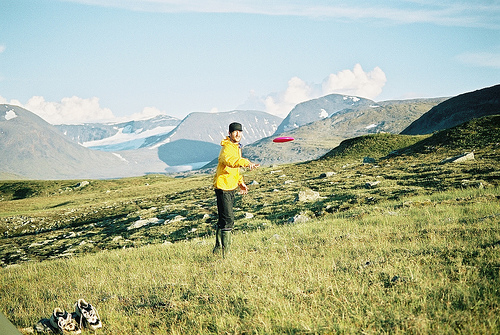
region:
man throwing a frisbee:
[196, 102, 336, 261]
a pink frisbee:
[256, 117, 305, 157]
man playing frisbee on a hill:
[191, 87, 343, 262]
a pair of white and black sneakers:
[34, 290, 116, 334]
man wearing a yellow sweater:
[208, 138, 254, 190]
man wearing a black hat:
[225, 122, 250, 134]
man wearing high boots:
[206, 225, 247, 261]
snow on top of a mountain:
[2, 96, 37, 136]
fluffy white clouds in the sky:
[280, 62, 398, 97]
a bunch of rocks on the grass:
[270, 163, 350, 225]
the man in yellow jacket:
[131, 89, 302, 323]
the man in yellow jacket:
[195, 112, 331, 326]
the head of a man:
[226, 119, 249, 144]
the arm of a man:
[219, 146, 244, 170]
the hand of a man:
[242, 158, 262, 175]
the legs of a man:
[208, 182, 243, 254]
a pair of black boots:
[207, 227, 232, 259]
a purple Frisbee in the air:
[271, 130, 296, 147]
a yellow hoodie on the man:
[209, 136, 251, 191]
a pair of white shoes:
[51, 290, 110, 333]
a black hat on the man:
[226, 116, 246, 132]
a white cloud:
[238, 55, 395, 118]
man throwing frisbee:
[210, 120, 296, 267]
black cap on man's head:
[226, 119, 244, 131]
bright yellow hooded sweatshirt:
[212, 133, 244, 190]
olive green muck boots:
[212, 225, 239, 259]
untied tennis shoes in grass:
[42, 297, 103, 333]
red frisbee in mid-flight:
[270, 133, 291, 141]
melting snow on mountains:
[46, 115, 194, 152]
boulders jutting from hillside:
[293, 181, 321, 218]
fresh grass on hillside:
[90, 250, 498, 332]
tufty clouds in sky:
[242, 60, 384, 109]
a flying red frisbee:
[272, 135, 295, 144]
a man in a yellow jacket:
[213, 120, 259, 255]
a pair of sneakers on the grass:
[46, 297, 103, 333]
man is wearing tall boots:
[211, 224, 236, 260]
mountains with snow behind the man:
[0, 82, 497, 184]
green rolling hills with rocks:
[2, 128, 498, 333]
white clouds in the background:
[234, 60, 389, 122]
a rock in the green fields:
[297, 184, 320, 201]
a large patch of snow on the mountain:
[70, 120, 175, 150]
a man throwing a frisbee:
[213, 122, 295, 261]